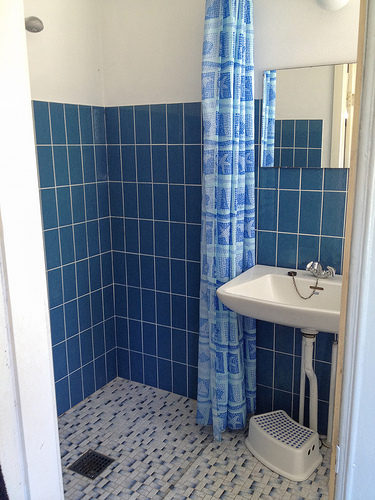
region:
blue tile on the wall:
[146, 99, 169, 147]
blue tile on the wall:
[150, 140, 169, 188]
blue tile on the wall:
[150, 180, 174, 225]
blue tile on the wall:
[151, 218, 169, 260]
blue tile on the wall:
[151, 254, 172, 297]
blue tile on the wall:
[153, 288, 175, 330]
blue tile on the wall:
[154, 322, 173, 368]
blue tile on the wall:
[155, 355, 173, 391]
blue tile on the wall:
[170, 325, 188, 370]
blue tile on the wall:
[170, 358, 188, 398]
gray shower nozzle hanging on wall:
[24, 15, 43, 33]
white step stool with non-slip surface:
[242, 407, 323, 481]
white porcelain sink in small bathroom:
[216, 265, 343, 332]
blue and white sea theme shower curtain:
[196, 1, 258, 440]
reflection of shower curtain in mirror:
[260, 68, 276, 166]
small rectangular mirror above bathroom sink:
[257, 60, 356, 167]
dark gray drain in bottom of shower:
[66, 448, 114, 480]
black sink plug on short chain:
[286, 270, 319, 299]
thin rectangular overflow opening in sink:
[308, 284, 323, 290]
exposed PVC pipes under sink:
[297, 328, 320, 432]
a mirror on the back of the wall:
[266, 65, 355, 164]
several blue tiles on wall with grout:
[110, 106, 191, 217]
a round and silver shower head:
[24, 14, 44, 37]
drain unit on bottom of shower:
[71, 451, 107, 475]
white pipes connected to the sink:
[300, 335, 315, 422]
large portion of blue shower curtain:
[203, 7, 256, 262]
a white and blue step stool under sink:
[252, 412, 312, 468]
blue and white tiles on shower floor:
[101, 395, 173, 449]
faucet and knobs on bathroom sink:
[300, 256, 336, 277]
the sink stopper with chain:
[292, 270, 318, 297]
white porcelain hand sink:
[215, 258, 339, 331]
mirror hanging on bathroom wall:
[261, 70, 349, 168]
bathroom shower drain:
[68, 443, 111, 477]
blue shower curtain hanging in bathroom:
[195, 2, 258, 442]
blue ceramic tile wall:
[30, 99, 195, 415]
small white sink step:
[244, 406, 321, 481]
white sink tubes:
[300, 334, 317, 425]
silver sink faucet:
[304, 261, 336, 280]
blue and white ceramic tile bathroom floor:
[55, 376, 335, 498]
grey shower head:
[21, 15, 43, 32]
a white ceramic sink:
[214, 260, 345, 341]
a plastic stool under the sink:
[244, 408, 324, 480]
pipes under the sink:
[297, 326, 339, 447]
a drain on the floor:
[69, 443, 117, 481]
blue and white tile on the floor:
[58, 374, 336, 499]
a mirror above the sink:
[260, 59, 359, 170]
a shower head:
[24, 14, 44, 34]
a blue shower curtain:
[198, 0, 256, 446]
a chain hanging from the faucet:
[286, 268, 319, 300]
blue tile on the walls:
[29, 97, 353, 445]